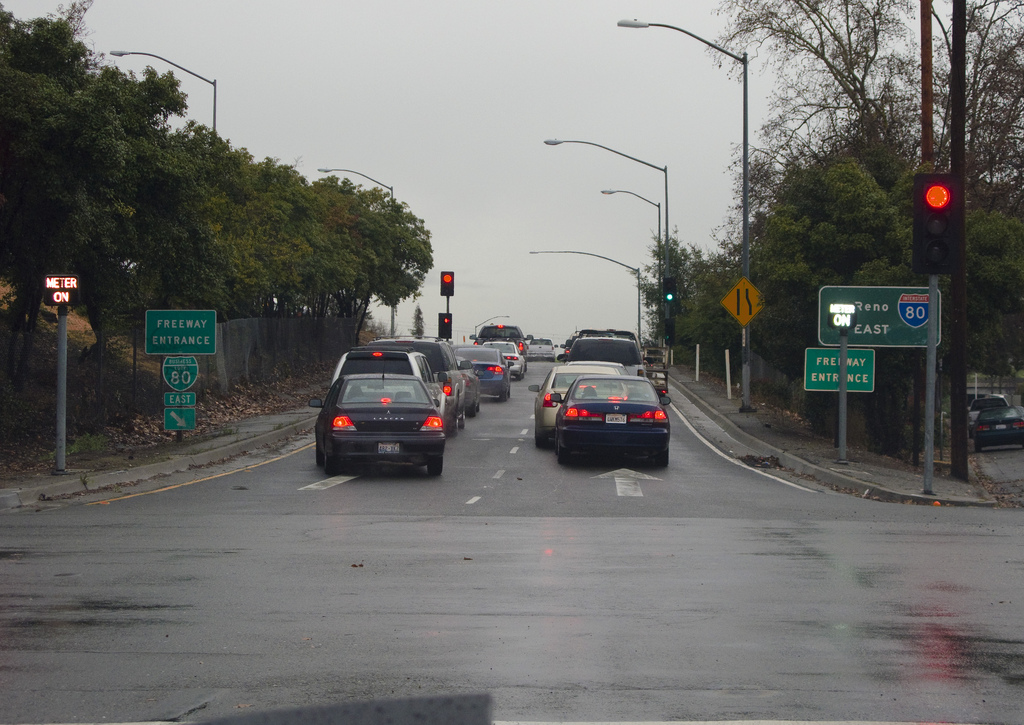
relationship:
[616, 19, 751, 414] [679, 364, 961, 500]
light on curb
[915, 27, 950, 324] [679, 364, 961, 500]
pole on curb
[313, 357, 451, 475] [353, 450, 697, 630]
car on street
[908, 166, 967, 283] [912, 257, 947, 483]
light on a pole